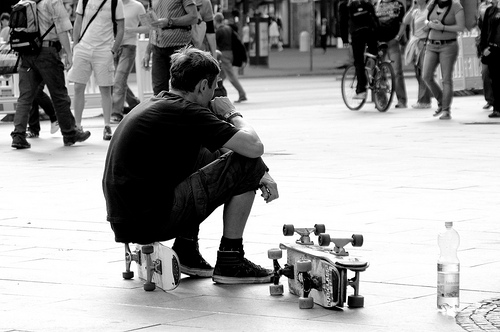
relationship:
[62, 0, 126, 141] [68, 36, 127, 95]
person wearing shorts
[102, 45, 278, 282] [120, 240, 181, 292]
man sitting on a skateboard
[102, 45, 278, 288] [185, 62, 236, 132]
man touching h face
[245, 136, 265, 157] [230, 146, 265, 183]
elbow on knee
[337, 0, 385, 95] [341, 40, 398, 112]
person riding bike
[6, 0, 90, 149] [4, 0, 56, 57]
person wearing backpack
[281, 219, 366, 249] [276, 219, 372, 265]
wheels on skateboard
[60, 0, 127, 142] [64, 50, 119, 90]
person wearing shorts